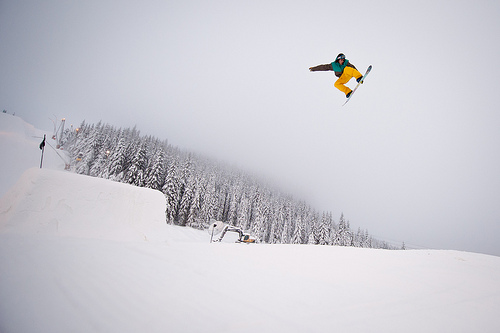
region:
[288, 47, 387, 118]
a man in the air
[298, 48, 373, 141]
a man on a snowboard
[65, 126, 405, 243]
pine trees covered with snow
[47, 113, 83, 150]
lights above the snow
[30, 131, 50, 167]
a metal post in the snow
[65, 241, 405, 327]
snow covers the ground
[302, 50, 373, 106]
a man is snowboarding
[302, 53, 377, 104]
a man is wearing yellow pants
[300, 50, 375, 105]
a man's right arm is extended out to the sidee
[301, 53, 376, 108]
the man's left hand is holding the snowboard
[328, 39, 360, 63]
His helmet is blue.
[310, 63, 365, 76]
The jacket is blue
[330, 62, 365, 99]
The pants are yellow.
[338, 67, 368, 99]
His boots are black.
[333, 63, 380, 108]
The board is black.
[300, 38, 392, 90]
He is in the air.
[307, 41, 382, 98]
He is doing a trick.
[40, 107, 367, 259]
The trees are snow covered.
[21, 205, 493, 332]
The ground is snow covered.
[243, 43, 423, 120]
He is snow boarding.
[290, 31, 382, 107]
man snowboarding in air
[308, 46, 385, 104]
man riding a snow board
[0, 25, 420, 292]
man going off snow jump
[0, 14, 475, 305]
man flying off snow jump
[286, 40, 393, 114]
man grabbing snow board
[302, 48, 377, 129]
man grabbing snow board in air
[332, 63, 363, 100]
yellow snow pants on man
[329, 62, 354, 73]
blue and brown snow jacket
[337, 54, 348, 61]
black snow hat on head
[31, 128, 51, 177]
black flag on top of jump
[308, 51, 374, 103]
A person in skies high in the air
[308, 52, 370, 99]
A person on a ski wearing yellow pants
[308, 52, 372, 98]
I person on a ski in a blue and brown jacket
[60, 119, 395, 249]
A large forest of trees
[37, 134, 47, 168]
A black flag on a pole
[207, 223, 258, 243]
A object in the white snow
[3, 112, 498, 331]
A large expanse of white snow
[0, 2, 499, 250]
A foggy overcast gray sky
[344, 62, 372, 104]
A white snow ski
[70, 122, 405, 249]
A large group of snow covered pine trees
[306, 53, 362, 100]
A snowboarder in mid air with yellow pants on.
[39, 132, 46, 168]
A pole with black flag on it.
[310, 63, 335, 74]
Extended right arm of a snowboarder.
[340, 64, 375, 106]
A snowboard on a man in the air.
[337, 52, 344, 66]
Head of a person in mid air.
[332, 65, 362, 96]
Yellow pants on a man in mid air.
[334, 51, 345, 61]
White goggles on the head of a man in mid air.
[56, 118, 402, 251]
All the trees behind the snowboarder.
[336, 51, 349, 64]
Head of a person in mid air.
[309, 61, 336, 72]
Arm that is extended of the person in mid air.